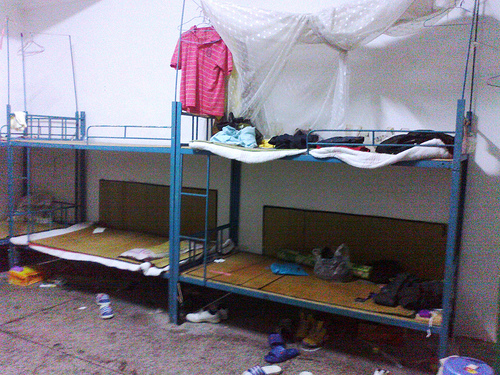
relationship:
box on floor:
[8, 242, 40, 296] [106, 306, 152, 358]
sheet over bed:
[204, 5, 481, 126] [173, 95, 474, 360]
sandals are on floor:
[264, 331, 307, 361] [189, 327, 247, 372]